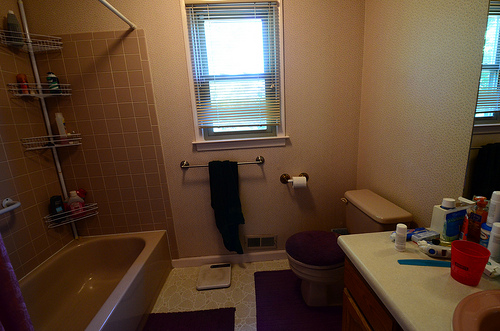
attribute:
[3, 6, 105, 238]
organizer — metal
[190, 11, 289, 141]
window — single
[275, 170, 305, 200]
napkin roll — white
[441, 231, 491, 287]
cup — red, plastic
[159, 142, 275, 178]
bar — silver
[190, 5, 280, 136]
blinds — open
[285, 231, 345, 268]
toilet cover — purple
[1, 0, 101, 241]
rack — steel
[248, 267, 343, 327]
rug — purple, brown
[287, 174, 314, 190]
toilet paper — rolled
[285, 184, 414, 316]
toilet — brown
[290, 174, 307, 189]
toilet paper — rolled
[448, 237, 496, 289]
cup — red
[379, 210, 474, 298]
thermometer — electric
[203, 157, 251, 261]
towel — hanging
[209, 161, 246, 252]
towel — brown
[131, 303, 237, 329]
rug — brown